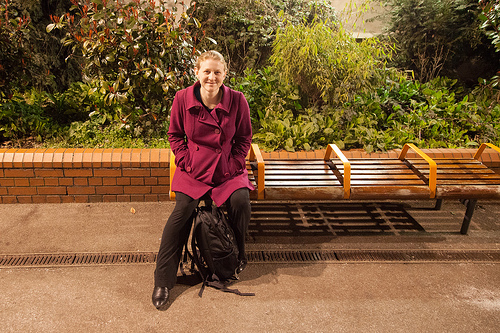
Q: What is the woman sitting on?
A: A bench.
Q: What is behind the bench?
A: Brick wall.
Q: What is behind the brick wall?
A: Plants and bushes.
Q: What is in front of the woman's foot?
A: A backpack.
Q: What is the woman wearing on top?
A: A jacket.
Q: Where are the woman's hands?
A: In her coat pockets.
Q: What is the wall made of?
A: Brick.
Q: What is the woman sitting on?
A: A bench.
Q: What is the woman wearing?
A: A red jacket and brown pants.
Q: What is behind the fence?
A: Bushes.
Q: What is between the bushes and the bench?
A: A brick wall.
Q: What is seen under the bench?
A: A shadow.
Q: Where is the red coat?
A: On the woman.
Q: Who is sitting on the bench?
A: The woman.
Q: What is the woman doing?
A: Sitting on a bench.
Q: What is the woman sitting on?
A: Bench.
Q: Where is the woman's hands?
A: In her pockets.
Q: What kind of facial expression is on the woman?
A: Smiling.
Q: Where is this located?
A: In the park.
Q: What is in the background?
A: Bushes and trees.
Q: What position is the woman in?
A: Sitting.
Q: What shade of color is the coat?
A: Pink.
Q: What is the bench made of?
A: Wood.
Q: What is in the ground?
A: A drain.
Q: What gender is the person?
A: Female.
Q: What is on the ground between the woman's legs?
A: Backpack.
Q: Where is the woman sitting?
A: Bench.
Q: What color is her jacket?
A: Red.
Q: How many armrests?
A: 5.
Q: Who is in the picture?
A: Woman.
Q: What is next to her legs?
A: Backpack.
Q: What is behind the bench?
A: Brick wall.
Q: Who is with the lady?
A: No one.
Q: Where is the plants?
A: Behind the wall.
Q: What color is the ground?
A: Brown.